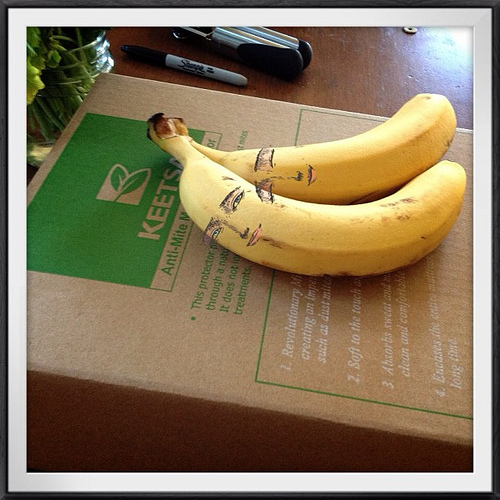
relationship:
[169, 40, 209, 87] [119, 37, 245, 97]
sharpie permanent marker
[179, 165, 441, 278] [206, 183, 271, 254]
banana with face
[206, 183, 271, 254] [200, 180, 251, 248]
face has eyes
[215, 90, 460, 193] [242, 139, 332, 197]
banana with face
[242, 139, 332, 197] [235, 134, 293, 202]
face has eyes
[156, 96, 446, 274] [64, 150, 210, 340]
two on box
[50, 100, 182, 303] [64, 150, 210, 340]
logo on box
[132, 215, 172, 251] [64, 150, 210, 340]
k on box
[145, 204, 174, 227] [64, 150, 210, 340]
e on box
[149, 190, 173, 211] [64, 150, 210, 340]
e on box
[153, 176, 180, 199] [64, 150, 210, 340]
t on box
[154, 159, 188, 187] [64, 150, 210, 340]
s on box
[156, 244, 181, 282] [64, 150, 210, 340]
anti on box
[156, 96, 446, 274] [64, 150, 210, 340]
bananas on box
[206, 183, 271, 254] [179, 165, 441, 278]
face on banana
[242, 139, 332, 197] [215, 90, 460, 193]
face on banana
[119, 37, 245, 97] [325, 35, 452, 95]
marker on table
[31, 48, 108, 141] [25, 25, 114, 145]
glass has glass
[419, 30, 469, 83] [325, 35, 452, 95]
reflection on table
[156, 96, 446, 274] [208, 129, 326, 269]
bananas have faces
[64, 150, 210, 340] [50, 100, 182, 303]
box has sign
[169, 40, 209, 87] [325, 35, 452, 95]
sharpie on table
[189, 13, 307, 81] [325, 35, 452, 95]
stapler on table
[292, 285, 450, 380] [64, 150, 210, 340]
writing on box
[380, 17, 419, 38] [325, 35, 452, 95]
button on table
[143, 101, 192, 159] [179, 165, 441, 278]
stem of banana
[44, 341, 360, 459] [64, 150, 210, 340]
side of box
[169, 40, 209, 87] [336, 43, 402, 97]
sharpie on desk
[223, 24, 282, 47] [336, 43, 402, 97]
pens on desk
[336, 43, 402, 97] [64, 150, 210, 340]
desk with box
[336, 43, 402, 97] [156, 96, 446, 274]
desk with bananas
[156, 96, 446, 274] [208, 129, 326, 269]
bananas with faces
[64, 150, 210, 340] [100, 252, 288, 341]
box with print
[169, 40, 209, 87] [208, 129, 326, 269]
sharpie drawn faces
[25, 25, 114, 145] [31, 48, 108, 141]
glass in glass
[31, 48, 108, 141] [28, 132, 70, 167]
glass of water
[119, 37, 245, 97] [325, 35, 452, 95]
pen on table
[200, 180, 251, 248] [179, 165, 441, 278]
eyes on banana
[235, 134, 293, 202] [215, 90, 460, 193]
eyes on banana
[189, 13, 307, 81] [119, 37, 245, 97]
object beside pen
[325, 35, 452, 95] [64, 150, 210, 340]
table beside box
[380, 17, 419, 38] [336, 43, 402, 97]
button on desk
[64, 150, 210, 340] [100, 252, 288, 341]
box has print